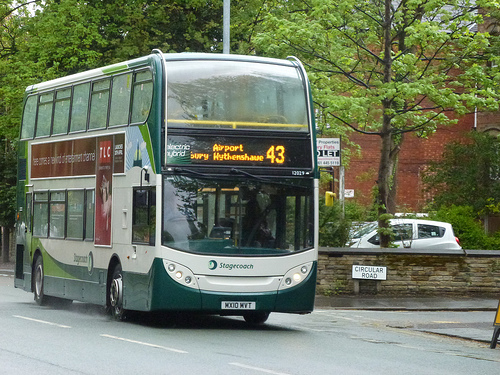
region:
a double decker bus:
[13, 46, 321, 324]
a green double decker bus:
[16, 51, 316, 323]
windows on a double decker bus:
[19, 63, 162, 141]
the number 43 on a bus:
[265, 141, 289, 171]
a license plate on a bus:
[218, 296, 260, 313]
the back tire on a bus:
[29, 255, 53, 305]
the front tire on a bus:
[105, 255, 128, 317]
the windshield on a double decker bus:
[165, 161, 320, 258]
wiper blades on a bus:
[166, 161, 307, 198]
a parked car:
[338, 210, 470, 257]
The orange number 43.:
[265, 143, 287, 164]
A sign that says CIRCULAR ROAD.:
[348, 263, 386, 292]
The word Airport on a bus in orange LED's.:
[211, 143, 243, 153]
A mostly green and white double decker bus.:
[11, 48, 321, 323]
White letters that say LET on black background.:
[322, 148, 339, 158]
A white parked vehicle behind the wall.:
[343, 214, 464, 256]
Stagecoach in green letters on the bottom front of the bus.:
[219, 261, 254, 271]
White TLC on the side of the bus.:
[98, 145, 111, 156]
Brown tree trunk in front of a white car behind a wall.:
[380, 26, 395, 246]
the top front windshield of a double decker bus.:
[161, 52, 310, 129]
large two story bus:
[124, 55, 324, 310]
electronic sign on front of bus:
[158, 125, 310, 173]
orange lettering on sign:
[180, 137, 289, 167]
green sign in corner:
[162, 137, 196, 165]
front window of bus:
[152, 183, 317, 257]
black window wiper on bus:
[169, 165, 220, 184]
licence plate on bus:
[218, 299, 266, 311]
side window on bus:
[128, 182, 156, 252]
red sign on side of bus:
[15, 134, 122, 239]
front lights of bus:
[163, 260, 194, 299]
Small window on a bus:
[130, 68, 153, 126]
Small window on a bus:
[102, 58, 133, 128]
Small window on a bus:
[85, 78, 112, 133]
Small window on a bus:
[65, 82, 98, 152]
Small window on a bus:
[47, 88, 75, 144]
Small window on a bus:
[33, 88, 60, 138]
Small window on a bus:
[10, 81, 40, 138]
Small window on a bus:
[78, 182, 98, 244]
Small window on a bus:
[60, 182, 87, 245]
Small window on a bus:
[31, 183, 71, 248]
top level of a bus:
[18, 53, 313, 140]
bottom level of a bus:
[16, 185, 318, 317]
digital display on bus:
[168, 131, 308, 170]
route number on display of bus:
[264, 140, 289, 170]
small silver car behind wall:
[352, 215, 462, 250]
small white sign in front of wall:
[351, 264, 387, 281]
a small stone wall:
[312, 248, 499, 295]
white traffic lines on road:
[10, 310, 295, 374]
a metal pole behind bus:
[219, 0, 231, 52]